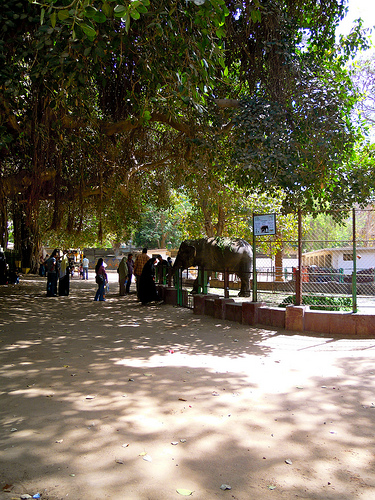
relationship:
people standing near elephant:
[117, 247, 172, 304] [166, 239, 249, 295]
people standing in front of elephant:
[44, 249, 182, 306] [172, 238, 257, 303]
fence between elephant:
[182, 267, 254, 300] [167, 237, 254, 298]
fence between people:
[182, 267, 254, 300] [95, 250, 176, 304]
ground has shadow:
[1, 270, 373, 497] [74, 362, 246, 409]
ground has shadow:
[1, 270, 373, 497] [177, 439, 294, 495]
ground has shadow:
[1, 270, 373, 497] [302, 370, 370, 442]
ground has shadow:
[1, 270, 373, 497] [177, 315, 277, 362]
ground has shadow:
[1, 270, 373, 497] [5, 318, 92, 350]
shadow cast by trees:
[74, 362, 246, 409] [35, 44, 286, 172]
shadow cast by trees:
[177, 439, 294, 495] [35, 44, 286, 172]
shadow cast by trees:
[302, 370, 370, 442] [35, 44, 286, 172]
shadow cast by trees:
[177, 315, 277, 362] [35, 44, 286, 172]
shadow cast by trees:
[5, 318, 92, 350] [35, 44, 286, 172]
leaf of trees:
[78, 22, 98, 39] [35, 44, 286, 172]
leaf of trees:
[130, 6, 141, 20] [35, 44, 286, 172]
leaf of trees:
[342, 220, 348, 228] [35, 44, 286, 172]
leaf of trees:
[37, 4, 45, 24] [35, 44, 286, 172]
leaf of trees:
[57, 9, 72, 19] [35, 44, 286, 172]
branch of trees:
[140, 98, 253, 140] [35, 44, 286, 172]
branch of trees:
[42, 197, 67, 233] [35, 44, 286, 172]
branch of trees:
[42, 0, 125, 97] [35, 44, 286, 172]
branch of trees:
[15, 141, 158, 202] [35, 44, 286, 172]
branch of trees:
[1, 104, 33, 151] [35, 44, 286, 172]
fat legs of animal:
[192, 265, 257, 303] [170, 237, 258, 299]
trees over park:
[2, 1, 374, 283] [2, 1, 373, 498]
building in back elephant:
[301, 200, 373, 278] [166, 234, 257, 301]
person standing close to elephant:
[118, 256, 127, 294] [167, 237, 254, 298]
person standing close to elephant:
[124, 252, 134, 293] [167, 237, 254, 298]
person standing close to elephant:
[133, 248, 148, 283] [167, 237, 254, 298]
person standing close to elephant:
[140, 257, 164, 305] [167, 237, 254, 298]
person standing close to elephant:
[153, 254, 166, 282] [167, 237, 254, 298]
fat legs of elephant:
[239, 275, 250, 297] [167, 237, 254, 298]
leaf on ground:
[175, 486, 195, 496] [1, 270, 373, 497]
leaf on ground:
[218, 480, 234, 490] [41, 341, 311, 441]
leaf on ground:
[179, 437, 187, 441] [1, 270, 373, 497]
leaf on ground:
[82, 393, 93, 401] [1, 270, 373, 497]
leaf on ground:
[124, 376, 137, 385] [140, 404, 154, 423]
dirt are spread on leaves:
[0, 268, 368, 498] [320, 384, 330, 387]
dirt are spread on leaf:
[0, 268, 368, 498] [124, 376, 137, 385]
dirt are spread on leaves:
[0, 268, 368, 498] [68, 371, 78, 377]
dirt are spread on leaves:
[0, 268, 368, 498] [166, 348, 176, 353]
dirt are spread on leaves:
[0, 268, 368, 498] [77, 353, 87, 357]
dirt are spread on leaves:
[0, 268, 368, 498] [121, 442, 129, 447]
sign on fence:
[252, 212, 278, 236] [114, 209, 374, 314]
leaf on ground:
[120, 441, 131, 447] [1, 270, 373, 497]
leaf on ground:
[8, 424, 19, 432] [1, 270, 373, 497]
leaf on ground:
[218, 480, 234, 490] [1, 270, 373, 497]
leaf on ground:
[283, 455, 292, 465] [1, 270, 373, 497]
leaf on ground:
[53, 438, 66, 443] [1, 270, 373, 497]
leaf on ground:
[290, 384, 309, 392] [1, 270, 373, 497]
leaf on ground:
[280, 454, 291, 472] [1, 270, 373, 497]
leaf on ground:
[118, 437, 132, 450] [1, 270, 373, 497]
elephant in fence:
[166, 239, 249, 295] [141, 240, 372, 316]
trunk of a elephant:
[158, 256, 179, 285] [168, 236, 299, 304]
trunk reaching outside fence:
[158, 256, 179, 285] [171, 253, 371, 310]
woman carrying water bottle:
[94, 257, 107, 300] [104, 282, 109, 293]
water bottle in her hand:
[104, 282, 109, 293] [103, 278, 108, 283]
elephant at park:
[166, 239, 249, 295] [1, 244, 372, 499]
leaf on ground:
[169, 438, 181, 444] [1, 270, 373, 497]